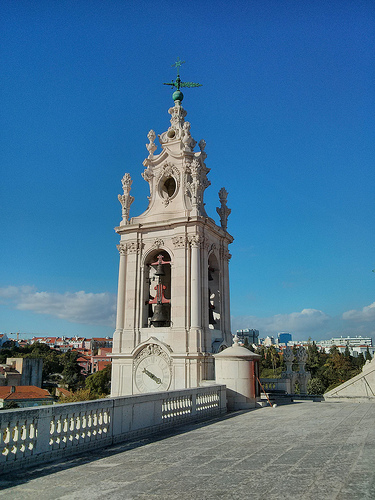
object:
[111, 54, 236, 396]
clock tower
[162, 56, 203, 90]
cross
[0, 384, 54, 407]
houses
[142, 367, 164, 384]
arms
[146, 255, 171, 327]
bell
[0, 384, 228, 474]
balustrade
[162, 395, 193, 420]
holes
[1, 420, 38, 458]
holes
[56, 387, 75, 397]
roof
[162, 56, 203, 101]
weather vane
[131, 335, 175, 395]
clock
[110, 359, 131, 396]
wall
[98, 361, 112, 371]
roof